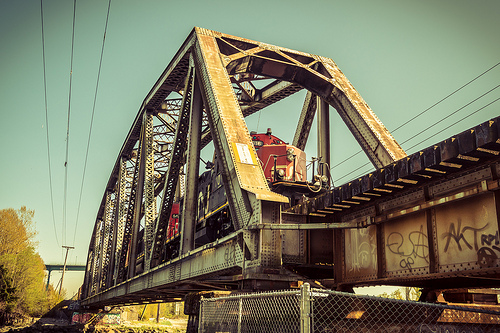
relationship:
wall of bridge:
[194, 27, 224, 82] [119, 209, 253, 260]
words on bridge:
[380, 226, 438, 263] [119, 209, 253, 260]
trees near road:
[4, 226, 55, 292] [33, 314, 62, 324]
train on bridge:
[258, 128, 323, 194] [119, 209, 253, 260]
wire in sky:
[91, 1, 116, 73] [328, 9, 391, 34]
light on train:
[267, 158, 284, 176] [258, 128, 323, 194]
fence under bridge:
[213, 296, 251, 311] [119, 209, 253, 260]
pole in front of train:
[55, 260, 65, 285] [258, 128, 323, 194]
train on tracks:
[258, 128, 323, 194] [344, 172, 375, 205]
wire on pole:
[91, 1, 116, 73] [55, 260, 65, 285]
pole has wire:
[55, 260, 65, 285] [91, 1, 116, 73]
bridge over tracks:
[119, 209, 253, 260] [344, 172, 375, 205]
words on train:
[380, 226, 438, 263] [258, 128, 323, 194]